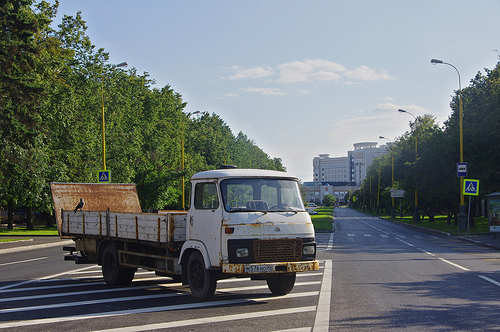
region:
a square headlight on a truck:
[236, 246, 249, 258]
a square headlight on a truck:
[302, 243, 316, 254]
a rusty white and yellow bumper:
[220, 259, 321, 274]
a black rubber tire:
[187, 248, 215, 300]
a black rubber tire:
[263, 269, 295, 292]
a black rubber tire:
[102, 261, 134, 282]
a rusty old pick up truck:
[53, 168, 320, 293]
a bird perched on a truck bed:
[73, 198, 87, 208]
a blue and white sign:
[458, 163, 466, 174]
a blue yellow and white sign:
[463, 177, 479, 194]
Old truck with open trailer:
[78, 144, 356, 309]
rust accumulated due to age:
[60, 174, 134, 225]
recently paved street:
[338, 182, 413, 329]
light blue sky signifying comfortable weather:
[188, 7, 489, 120]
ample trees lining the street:
[22, 46, 211, 168]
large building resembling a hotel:
[327, 142, 448, 207]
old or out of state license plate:
[247, 263, 278, 274]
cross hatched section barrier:
[49, 270, 167, 330]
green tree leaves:
[71, 93, 219, 174]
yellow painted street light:
[456, 93, 498, 196]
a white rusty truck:
[19, 167, 321, 294]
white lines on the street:
[31, 277, 331, 329]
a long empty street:
[332, 167, 494, 304]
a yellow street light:
[417, 42, 474, 227]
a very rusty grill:
[202, 230, 320, 272]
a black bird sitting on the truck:
[56, 193, 92, 210]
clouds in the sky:
[178, 45, 391, 120]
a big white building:
[301, 137, 387, 199]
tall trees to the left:
[4, 60, 184, 193]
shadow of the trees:
[331, 246, 486, 320]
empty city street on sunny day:
[0, 0, 497, 330]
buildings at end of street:
[300, 139, 396, 204]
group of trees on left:
[0, 0, 286, 231]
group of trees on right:
[348, 58, 498, 226]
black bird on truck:
[72, 196, 84, 213]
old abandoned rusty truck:
[48, 167, 319, 299]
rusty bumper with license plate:
[219, 259, 319, 274]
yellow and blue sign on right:
[461, 177, 478, 194]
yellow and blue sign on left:
[98, 168, 110, 183]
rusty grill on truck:
[250, 236, 301, 260]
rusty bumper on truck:
[219, 261, 319, 275]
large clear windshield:
[219, 176, 305, 212]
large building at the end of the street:
[313, 139, 398, 205]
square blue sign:
[461, 177, 481, 196]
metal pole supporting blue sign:
[466, 194, 473, 237]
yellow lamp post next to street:
[429, 57, 469, 208]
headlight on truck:
[234, 246, 250, 257]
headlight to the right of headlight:
[302, 245, 317, 255]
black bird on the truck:
[72, 197, 87, 211]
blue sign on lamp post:
[96, 167, 113, 182]